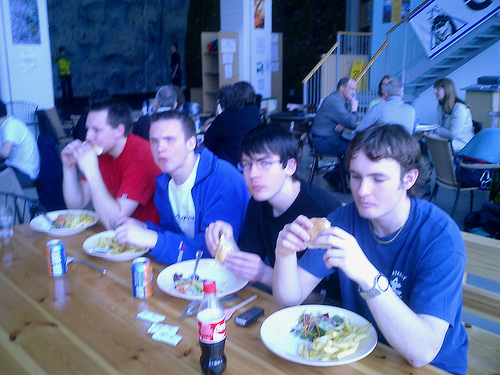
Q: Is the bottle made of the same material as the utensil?
A: No, the bottle is made of plastic and the utensil is made of metal.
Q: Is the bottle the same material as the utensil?
A: No, the bottle is made of plastic and the utensil is made of metal.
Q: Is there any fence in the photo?
A: No, there are no fences.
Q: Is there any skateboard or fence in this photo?
A: No, there are no fences or skateboards.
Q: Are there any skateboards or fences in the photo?
A: No, there are no fences or skateboards.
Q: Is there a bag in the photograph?
A: No, there are no bags.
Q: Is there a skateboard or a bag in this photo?
A: No, there are no bags or skateboards.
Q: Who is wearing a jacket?
A: The guy is wearing a jacket.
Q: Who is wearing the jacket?
A: The guy is wearing a jacket.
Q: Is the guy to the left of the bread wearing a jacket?
A: Yes, the guy is wearing a jacket.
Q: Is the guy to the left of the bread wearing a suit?
A: No, the guy is wearing a jacket.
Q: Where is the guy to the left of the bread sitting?
A: The guy is sitting at the table.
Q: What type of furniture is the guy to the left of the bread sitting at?
A: The guy is sitting at the table.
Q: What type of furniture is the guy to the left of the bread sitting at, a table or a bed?
A: The guy is sitting at a table.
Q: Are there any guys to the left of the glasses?
A: Yes, there is a guy to the left of the glasses.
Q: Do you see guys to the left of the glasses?
A: Yes, there is a guy to the left of the glasses.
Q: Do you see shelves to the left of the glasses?
A: No, there is a guy to the left of the glasses.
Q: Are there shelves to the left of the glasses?
A: No, there is a guy to the left of the glasses.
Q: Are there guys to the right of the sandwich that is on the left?
A: Yes, there is a guy to the right of the sandwich.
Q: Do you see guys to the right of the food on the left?
A: Yes, there is a guy to the right of the sandwich.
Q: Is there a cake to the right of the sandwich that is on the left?
A: No, there is a guy to the right of the sandwich.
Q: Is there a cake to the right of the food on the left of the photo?
A: No, there is a guy to the right of the sandwich.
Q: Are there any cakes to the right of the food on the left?
A: No, there is a guy to the right of the sandwich.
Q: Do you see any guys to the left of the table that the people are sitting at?
A: Yes, there is a guy to the left of the table.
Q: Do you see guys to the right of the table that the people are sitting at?
A: No, the guy is to the left of the table.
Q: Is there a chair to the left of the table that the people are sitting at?
A: No, there is a guy to the left of the table.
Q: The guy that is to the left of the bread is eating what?
A: The guy is eating lunch.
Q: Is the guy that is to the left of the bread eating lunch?
A: Yes, the guy is eating lunch.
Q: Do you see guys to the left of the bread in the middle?
A: Yes, there is a guy to the left of the bread.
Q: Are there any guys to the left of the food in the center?
A: Yes, there is a guy to the left of the bread.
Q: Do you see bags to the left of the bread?
A: No, there is a guy to the left of the bread.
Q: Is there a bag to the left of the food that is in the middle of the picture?
A: No, there is a guy to the left of the bread.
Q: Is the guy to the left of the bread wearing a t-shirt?
A: Yes, the guy is wearing a t-shirt.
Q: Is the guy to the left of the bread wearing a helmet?
A: No, the guy is wearing a t-shirt.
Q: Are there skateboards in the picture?
A: No, there are no skateboards.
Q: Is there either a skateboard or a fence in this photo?
A: No, there are no skateboards or fences.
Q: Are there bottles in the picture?
A: Yes, there is a bottle.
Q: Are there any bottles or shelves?
A: Yes, there is a bottle.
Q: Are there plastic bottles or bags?
A: Yes, there is a plastic bottle.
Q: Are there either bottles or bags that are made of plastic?
A: Yes, the bottle is made of plastic.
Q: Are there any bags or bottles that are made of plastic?
A: Yes, the bottle is made of plastic.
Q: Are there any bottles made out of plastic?
A: Yes, there is a bottle that is made of plastic.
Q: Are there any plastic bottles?
A: Yes, there is a bottle that is made of plastic.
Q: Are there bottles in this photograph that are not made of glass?
A: Yes, there is a bottle that is made of plastic.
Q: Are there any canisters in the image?
A: No, there are no canisters.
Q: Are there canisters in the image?
A: No, there are no canisters.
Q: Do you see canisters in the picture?
A: No, there are no canisters.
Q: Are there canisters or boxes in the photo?
A: No, there are no canisters or boxes.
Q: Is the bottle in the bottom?
A: Yes, the bottle is in the bottom of the image.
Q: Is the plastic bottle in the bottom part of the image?
A: Yes, the bottle is in the bottom of the image.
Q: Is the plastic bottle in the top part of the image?
A: No, the bottle is in the bottom of the image.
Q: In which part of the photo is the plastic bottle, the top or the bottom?
A: The bottle is in the bottom of the image.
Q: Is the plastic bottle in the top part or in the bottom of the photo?
A: The bottle is in the bottom of the image.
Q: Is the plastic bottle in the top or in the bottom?
A: The bottle is in the bottom of the image.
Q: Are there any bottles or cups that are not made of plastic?
A: No, there is a bottle but it is made of plastic.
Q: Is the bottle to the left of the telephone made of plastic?
A: Yes, the bottle is made of plastic.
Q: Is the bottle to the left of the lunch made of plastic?
A: Yes, the bottle is made of plastic.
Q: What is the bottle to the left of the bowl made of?
A: The bottle is made of plastic.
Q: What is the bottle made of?
A: The bottle is made of plastic.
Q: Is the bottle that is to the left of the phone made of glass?
A: No, the bottle is made of plastic.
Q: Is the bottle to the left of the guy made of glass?
A: No, the bottle is made of plastic.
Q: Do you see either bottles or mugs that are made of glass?
A: No, there is a bottle but it is made of plastic.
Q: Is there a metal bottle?
A: No, there is a bottle but it is made of plastic.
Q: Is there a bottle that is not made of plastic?
A: No, there is a bottle but it is made of plastic.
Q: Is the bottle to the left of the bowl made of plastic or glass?
A: The bottle is made of plastic.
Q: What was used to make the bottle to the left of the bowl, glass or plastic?
A: The bottle is made of plastic.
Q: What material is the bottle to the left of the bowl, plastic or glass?
A: The bottle is made of plastic.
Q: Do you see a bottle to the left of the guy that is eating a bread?
A: Yes, there is a bottle to the left of the guy.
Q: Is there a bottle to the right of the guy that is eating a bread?
A: No, the bottle is to the left of the guy.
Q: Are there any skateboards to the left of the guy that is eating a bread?
A: No, there is a bottle to the left of the guy.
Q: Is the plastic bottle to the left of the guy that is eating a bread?
A: Yes, the bottle is to the left of the guy.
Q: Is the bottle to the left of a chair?
A: No, the bottle is to the left of the guy.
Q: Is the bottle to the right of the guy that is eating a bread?
A: No, the bottle is to the left of the guy.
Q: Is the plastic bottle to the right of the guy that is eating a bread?
A: No, the bottle is to the left of the guy.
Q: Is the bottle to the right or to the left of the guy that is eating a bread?
A: The bottle is to the left of the guy.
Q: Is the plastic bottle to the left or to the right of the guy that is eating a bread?
A: The bottle is to the left of the guy.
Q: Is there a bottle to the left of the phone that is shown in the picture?
A: Yes, there is a bottle to the left of the phone.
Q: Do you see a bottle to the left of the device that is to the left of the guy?
A: Yes, there is a bottle to the left of the phone.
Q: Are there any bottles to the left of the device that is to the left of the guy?
A: Yes, there is a bottle to the left of the phone.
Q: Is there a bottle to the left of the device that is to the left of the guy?
A: Yes, there is a bottle to the left of the phone.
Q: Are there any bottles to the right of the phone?
A: No, the bottle is to the left of the phone.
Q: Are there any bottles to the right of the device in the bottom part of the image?
A: No, the bottle is to the left of the phone.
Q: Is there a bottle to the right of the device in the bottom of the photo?
A: No, the bottle is to the left of the phone.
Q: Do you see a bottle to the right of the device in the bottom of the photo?
A: No, the bottle is to the left of the phone.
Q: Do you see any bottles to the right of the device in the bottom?
A: No, the bottle is to the left of the phone.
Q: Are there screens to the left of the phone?
A: No, there is a bottle to the left of the phone.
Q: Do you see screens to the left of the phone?
A: No, there is a bottle to the left of the phone.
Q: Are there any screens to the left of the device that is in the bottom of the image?
A: No, there is a bottle to the left of the phone.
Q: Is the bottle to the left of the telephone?
A: Yes, the bottle is to the left of the telephone.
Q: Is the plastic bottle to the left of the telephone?
A: Yes, the bottle is to the left of the telephone.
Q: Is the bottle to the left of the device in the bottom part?
A: Yes, the bottle is to the left of the telephone.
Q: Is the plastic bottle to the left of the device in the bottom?
A: Yes, the bottle is to the left of the telephone.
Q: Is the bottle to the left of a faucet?
A: No, the bottle is to the left of the telephone.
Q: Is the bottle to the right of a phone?
A: No, the bottle is to the left of a phone.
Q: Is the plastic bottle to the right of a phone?
A: No, the bottle is to the left of a phone.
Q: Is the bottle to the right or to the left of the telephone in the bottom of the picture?
A: The bottle is to the left of the telephone.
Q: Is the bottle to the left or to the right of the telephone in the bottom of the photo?
A: The bottle is to the left of the telephone.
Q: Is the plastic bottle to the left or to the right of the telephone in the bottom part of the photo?
A: The bottle is to the left of the telephone.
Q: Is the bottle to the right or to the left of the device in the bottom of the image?
A: The bottle is to the left of the telephone.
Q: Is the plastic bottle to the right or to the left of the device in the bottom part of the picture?
A: The bottle is to the left of the telephone.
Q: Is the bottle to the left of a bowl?
A: Yes, the bottle is to the left of a bowl.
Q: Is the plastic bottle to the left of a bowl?
A: Yes, the bottle is to the left of a bowl.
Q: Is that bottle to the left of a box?
A: No, the bottle is to the left of a bowl.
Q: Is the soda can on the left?
A: Yes, the soda can is on the left of the image.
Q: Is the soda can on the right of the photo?
A: No, the soda can is on the left of the image.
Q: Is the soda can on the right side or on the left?
A: The soda can is on the left of the image.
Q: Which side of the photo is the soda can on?
A: The soda can is on the left of the image.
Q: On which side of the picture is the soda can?
A: The soda can is on the left of the image.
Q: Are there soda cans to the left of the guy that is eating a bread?
A: Yes, there is a soda can to the left of the guy.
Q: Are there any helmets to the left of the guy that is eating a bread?
A: No, there is a soda can to the left of the guy.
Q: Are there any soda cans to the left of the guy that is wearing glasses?
A: Yes, there is a soda can to the left of the guy.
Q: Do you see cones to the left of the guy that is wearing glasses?
A: No, there is a soda can to the left of the guy.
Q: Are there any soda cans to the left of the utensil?
A: Yes, there is a soda can to the left of the utensil.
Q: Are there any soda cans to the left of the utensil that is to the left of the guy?
A: Yes, there is a soda can to the left of the utensil.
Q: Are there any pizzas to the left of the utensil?
A: No, there is a soda can to the left of the utensil.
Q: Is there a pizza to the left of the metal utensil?
A: No, there is a soda can to the left of the utensil.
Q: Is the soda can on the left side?
A: Yes, the soda can is on the left of the image.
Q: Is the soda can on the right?
A: No, the soda can is on the left of the image.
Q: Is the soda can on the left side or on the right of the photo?
A: The soda can is on the left of the image.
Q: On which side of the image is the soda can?
A: The soda can is on the left of the image.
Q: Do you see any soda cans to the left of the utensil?
A: Yes, there is a soda can to the left of the utensil.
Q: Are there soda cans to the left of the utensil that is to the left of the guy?
A: Yes, there is a soda can to the left of the utensil.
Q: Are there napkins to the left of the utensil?
A: No, there is a soda can to the left of the utensil.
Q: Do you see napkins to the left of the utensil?
A: No, there is a soda can to the left of the utensil.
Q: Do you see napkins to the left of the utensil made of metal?
A: No, there is a soda can to the left of the utensil.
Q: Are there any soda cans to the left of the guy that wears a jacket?
A: Yes, there is a soda can to the left of the guy.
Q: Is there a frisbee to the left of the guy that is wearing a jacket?
A: No, there is a soda can to the left of the guy.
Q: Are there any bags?
A: No, there are no bags.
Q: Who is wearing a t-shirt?
A: The guy is wearing a t-shirt.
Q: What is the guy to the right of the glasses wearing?
A: The guy is wearing a tee shirt.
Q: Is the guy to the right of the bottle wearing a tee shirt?
A: Yes, the guy is wearing a tee shirt.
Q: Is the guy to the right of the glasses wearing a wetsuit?
A: No, the guy is wearing a tee shirt.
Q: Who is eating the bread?
A: The guy is eating the bread.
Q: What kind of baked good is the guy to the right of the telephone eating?
A: The guy is eating a bread.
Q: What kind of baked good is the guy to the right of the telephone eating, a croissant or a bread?
A: The guy is eating a bread.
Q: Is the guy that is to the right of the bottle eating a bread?
A: Yes, the guy is eating a bread.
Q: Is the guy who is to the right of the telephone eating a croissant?
A: No, the guy is eating a bread.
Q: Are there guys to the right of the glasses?
A: Yes, there is a guy to the right of the glasses.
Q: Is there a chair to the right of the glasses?
A: No, there is a guy to the right of the glasses.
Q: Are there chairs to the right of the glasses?
A: No, there is a guy to the right of the glasses.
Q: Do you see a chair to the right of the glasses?
A: No, there is a guy to the right of the glasses.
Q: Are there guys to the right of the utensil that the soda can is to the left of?
A: Yes, there is a guy to the right of the utensil.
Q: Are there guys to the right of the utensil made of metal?
A: Yes, there is a guy to the right of the utensil.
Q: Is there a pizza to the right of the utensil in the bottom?
A: No, there is a guy to the right of the utensil.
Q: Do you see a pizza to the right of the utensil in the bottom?
A: No, there is a guy to the right of the utensil.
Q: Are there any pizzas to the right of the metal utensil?
A: No, there is a guy to the right of the utensil.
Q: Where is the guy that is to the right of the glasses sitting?
A: The guy is sitting at the table.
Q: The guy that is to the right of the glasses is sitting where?
A: The guy is sitting at the table.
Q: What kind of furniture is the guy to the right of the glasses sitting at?
A: The guy is sitting at the table.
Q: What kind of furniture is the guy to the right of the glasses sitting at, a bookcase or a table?
A: The guy is sitting at a table.